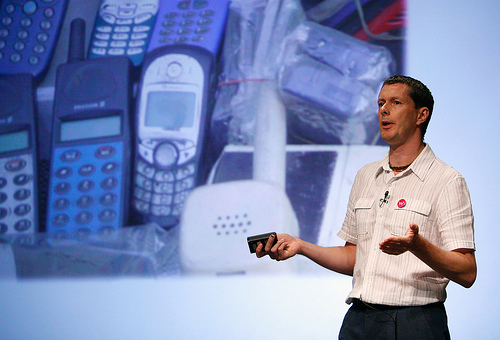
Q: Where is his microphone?
A: On his shirt.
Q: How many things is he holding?
A: One.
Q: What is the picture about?
A: Cell Phones.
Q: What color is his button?
A: Red.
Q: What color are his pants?
A: Black.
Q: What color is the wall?
A: White.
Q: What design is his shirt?
A: Stripes.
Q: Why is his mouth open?
A: He is talking.